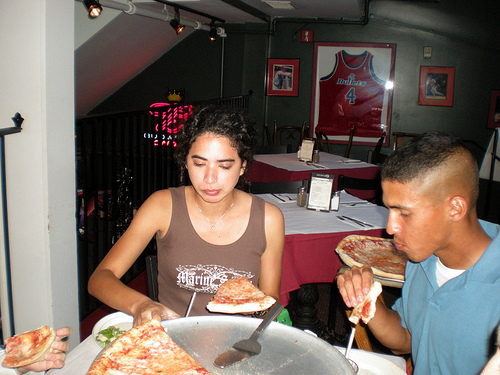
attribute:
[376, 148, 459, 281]
guy — chewing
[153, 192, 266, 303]
top — brown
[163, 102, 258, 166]
hair — curly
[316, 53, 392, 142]
jersey — red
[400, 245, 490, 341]
shirt — blue